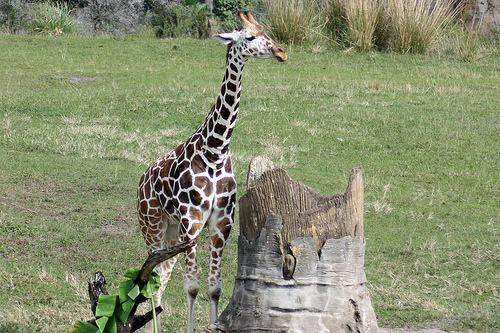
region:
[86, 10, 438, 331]
the giraffe by a tree stump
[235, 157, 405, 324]
an old tree stump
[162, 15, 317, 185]
the giraffe is looking over a tree stump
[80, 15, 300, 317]
this giraffe is observing something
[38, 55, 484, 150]
the grass as brown spots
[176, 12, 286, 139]
the giraffe's kneck is long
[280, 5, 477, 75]
brush in the background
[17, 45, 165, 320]
the grass is sparse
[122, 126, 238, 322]
the legs are long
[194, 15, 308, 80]
the head of the giraffe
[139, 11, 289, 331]
girafe standing near the trunk of a tree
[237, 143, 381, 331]
tree stump means someone cut this tree down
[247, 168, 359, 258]
bark of the stump is peeling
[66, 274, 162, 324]
withering plant near tree stump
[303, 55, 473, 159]
grass that isn't so bright green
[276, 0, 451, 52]
high grass growing off in the distance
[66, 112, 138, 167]
some brown grass means it's dead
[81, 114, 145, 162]
brown grass also might mean the area hasn't had rain in a while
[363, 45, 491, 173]
grass looks cut, not natural...so the giraffe is probably not in its natural habitat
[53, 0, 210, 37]
low shrubs off in the distance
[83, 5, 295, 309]
the giraffe is brown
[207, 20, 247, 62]
giraffe's ear is white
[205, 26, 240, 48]
giraffe's ear is white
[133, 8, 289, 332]
Giraffe standing next to a trunk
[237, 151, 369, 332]
Broken tree trunk next to a giraffe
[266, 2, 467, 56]
Thick dry foliage at the background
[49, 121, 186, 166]
Dry brown grass behind the giraffe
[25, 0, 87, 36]
Green foliage in the background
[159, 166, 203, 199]
Dark brown spots on the body of the giraffe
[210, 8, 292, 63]
Giraffe's head loooking on the right side of the trunk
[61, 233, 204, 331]
Green plant with brown branches near the giraffe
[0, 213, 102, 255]
Green grass near the giraffe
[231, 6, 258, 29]
Giraffe's horn on his head